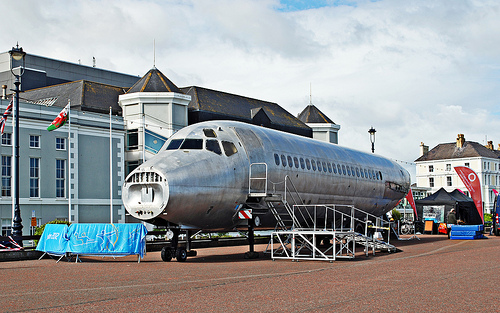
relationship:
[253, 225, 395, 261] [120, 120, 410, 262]
ramp leads up to airplane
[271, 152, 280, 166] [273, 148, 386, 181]
window in row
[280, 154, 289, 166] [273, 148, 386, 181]
window in row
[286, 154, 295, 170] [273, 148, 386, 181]
window in row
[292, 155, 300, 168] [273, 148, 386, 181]
window in row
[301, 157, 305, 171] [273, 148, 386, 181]
window in row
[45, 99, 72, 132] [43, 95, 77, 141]
flag wavy in wind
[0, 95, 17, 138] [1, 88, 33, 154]
union jack in wind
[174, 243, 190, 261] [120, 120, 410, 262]
wheel attached to airplane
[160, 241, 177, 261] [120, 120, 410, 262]
wheel attached to airplane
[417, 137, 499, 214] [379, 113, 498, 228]
building in background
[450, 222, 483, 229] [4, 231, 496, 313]
box on ground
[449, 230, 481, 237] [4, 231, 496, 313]
box on ground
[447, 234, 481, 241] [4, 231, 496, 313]
box on ground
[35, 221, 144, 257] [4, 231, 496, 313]
sign on ground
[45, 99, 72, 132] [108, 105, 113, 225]
flag hanging on pole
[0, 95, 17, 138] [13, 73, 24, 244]
union jack hanging on pole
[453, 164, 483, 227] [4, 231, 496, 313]
sign on side of ground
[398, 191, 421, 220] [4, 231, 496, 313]
sign on side of ground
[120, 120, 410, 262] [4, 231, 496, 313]
airplane on ground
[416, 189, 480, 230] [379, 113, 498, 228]
tent in background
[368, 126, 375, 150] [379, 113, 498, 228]
light post in back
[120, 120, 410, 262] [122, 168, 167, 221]
airplane without propeller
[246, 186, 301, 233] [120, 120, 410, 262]
steps are leading up to airplane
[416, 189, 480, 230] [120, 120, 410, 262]
tent behind airplane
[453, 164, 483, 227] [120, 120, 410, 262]
sign behind airplane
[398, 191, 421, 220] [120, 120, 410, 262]
sign behind airplane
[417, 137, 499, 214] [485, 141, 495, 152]
building has chimney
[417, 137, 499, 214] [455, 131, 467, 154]
building has chimney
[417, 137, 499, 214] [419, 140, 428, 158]
building has chimney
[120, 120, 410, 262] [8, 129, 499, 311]
airplane on display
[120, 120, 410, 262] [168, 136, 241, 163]
airplane has cockpit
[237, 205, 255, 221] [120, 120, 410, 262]
sign underside airplane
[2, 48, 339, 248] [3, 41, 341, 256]
building painted grey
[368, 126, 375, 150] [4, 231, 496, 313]
light post on side of ground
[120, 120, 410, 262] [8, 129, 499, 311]
airplane on exhibit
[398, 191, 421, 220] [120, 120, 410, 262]
sign at end of airplane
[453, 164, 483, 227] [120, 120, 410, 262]
sign at end of airplane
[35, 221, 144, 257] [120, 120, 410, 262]
sign at front of airplane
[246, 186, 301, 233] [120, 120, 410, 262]
steps are leading to airplane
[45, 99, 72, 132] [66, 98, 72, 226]
flag on pole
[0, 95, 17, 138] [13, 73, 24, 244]
union jack at pole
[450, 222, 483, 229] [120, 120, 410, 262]
box at end of airplane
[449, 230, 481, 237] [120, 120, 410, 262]
box at end of airplane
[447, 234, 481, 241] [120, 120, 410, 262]
box at end of airplane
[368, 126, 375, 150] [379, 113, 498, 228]
light post in background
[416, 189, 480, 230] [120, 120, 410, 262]
tent at rear of airplane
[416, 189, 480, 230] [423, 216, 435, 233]
tent has sign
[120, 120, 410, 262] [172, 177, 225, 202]
airplane has part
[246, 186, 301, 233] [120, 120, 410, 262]
steps are up to airplane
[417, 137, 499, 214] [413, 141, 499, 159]
building has roof